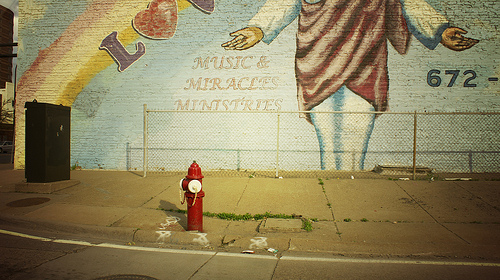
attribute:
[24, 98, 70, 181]
case — metal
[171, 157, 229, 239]
hydrant — metal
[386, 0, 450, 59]
arm — extended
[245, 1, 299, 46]
arm — extended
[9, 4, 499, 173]
mural wall — painted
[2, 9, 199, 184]
drawing — rainbow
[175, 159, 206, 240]
hydrant — red